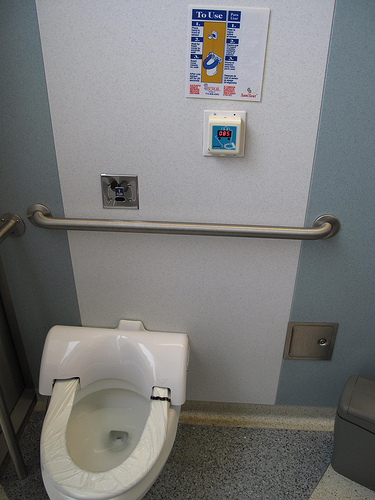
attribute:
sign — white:
[184, 5, 272, 101]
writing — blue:
[187, 24, 242, 86]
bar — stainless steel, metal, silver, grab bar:
[25, 209, 342, 241]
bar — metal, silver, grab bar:
[3, 210, 28, 242]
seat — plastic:
[41, 378, 168, 499]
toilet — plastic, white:
[37, 319, 189, 499]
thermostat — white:
[203, 107, 247, 159]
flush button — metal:
[97, 174, 138, 211]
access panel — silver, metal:
[280, 320, 338, 363]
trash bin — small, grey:
[331, 371, 372, 491]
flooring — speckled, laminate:
[0, 407, 340, 497]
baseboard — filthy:
[181, 402, 344, 428]